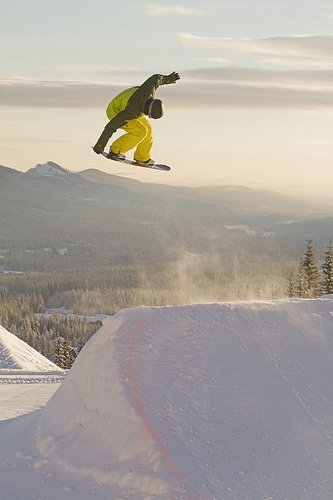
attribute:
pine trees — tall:
[280, 225, 331, 302]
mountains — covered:
[11, 151, 313, 298]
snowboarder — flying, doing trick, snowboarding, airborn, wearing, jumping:
[84, 66, 193, 184]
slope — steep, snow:
[3, 316, 64, 400]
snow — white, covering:
[1, 413, 46, 463]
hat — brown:
[140, 97, 162, 116]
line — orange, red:
[1, 363, 67, 382]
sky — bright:
[4, 10, 319, 112]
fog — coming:
[225, 136, 326, 226]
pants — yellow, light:
[102, 116, 165, 177]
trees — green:
[12, 319, 96, 366]